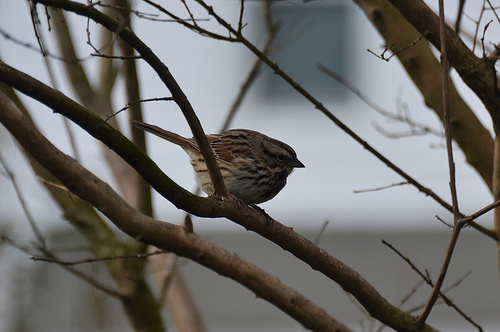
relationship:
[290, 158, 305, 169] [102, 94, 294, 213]
beak on bird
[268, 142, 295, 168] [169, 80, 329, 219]
eye on bird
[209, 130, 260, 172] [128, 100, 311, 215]
wing on bird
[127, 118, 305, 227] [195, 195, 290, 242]
bird sitting on branch part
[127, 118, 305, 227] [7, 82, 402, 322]
bird sitting on branch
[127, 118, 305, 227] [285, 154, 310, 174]
bird has beak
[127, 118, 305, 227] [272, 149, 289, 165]
bird has eye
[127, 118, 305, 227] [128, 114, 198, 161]
bird has tail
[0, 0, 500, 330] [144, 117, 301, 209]
branch beneath bird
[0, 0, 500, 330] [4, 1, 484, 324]
branch on tree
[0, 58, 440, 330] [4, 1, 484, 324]
branch on tree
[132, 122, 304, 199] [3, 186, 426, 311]
bird on a branch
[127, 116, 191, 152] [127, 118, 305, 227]
tail of bird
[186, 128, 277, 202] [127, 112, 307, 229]
body of bird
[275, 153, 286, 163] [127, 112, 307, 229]
eye of bird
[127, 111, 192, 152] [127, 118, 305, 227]
tail of bird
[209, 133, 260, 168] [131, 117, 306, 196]
wing on bird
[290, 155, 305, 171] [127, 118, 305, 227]
beak on bird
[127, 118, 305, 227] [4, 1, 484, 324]
bird in a tree